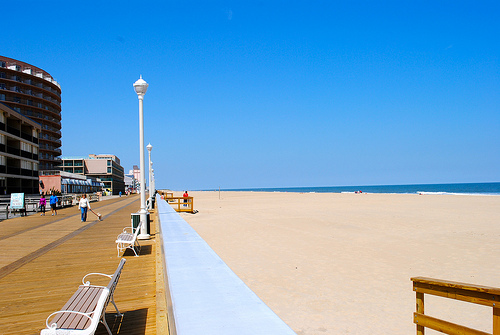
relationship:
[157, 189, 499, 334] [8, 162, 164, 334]
sand in deck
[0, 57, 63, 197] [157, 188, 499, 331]
hotel in beach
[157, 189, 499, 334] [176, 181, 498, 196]
sand in water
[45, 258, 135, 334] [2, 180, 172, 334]
bench in deck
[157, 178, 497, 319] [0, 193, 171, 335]
beach in boardwalk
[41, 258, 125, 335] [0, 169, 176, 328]
bench in boardwalk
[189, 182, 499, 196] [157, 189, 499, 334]
ocean in sand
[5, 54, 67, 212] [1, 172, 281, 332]
hotel in boardwalk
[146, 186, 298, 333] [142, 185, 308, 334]
board of wall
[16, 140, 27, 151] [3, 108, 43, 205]
window of building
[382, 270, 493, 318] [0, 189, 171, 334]
handrail at boardwalk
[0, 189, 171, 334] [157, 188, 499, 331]
boardwalk next to beach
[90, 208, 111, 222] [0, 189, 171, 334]
dog walking on boardwalk